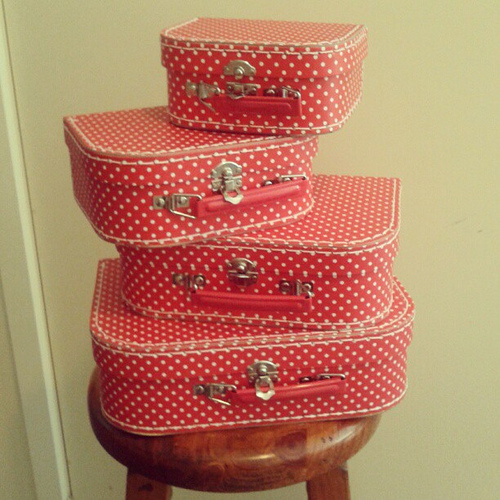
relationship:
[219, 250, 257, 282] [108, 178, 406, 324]
latch on luggage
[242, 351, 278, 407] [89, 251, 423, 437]
latch on luggage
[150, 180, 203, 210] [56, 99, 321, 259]
latch on luggage